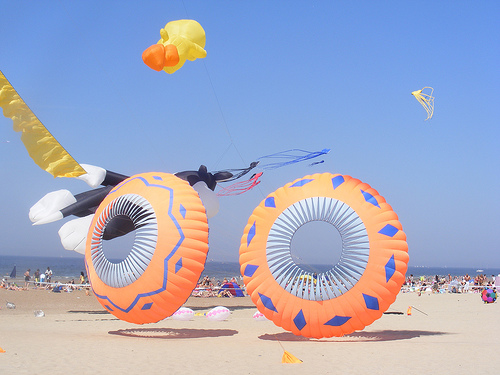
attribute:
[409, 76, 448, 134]
kite — flying, white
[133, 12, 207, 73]
kite — yellow, flying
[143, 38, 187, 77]
feet — orange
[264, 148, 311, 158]
streamer — blue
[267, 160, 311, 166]
streamer — blue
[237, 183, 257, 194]
streamer — red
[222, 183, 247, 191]
streamer — red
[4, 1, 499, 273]
sky — blue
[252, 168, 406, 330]
kite — blue, orange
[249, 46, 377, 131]
sky — clear, blue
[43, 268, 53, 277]
shirt — white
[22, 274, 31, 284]
shorts — black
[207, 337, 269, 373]
sand — beach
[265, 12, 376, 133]
sky — clear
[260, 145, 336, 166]
kite — wavy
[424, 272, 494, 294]
beach — full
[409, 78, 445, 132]
kite — yellow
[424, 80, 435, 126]
tails — long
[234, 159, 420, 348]
kite — circular, orange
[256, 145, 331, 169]
kite — blue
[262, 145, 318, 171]
tails — long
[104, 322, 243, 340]
shadow — kite's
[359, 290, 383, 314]
shape — diamond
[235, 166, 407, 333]
kite — orange, blue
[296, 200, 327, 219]
pattern — striped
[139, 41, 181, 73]
feet — orange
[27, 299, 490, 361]
sand — brown